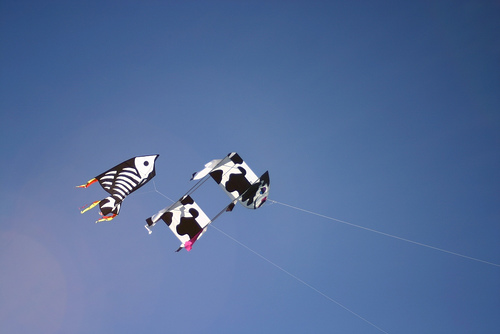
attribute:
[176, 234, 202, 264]
tail — pink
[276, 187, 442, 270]
line — white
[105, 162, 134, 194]
line — white